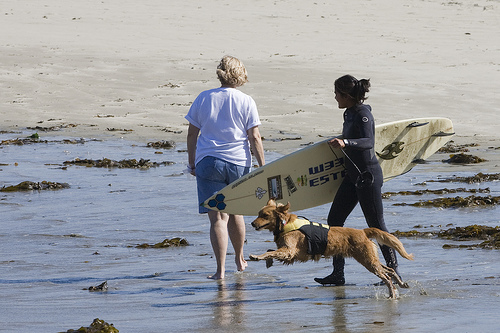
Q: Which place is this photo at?
A: It is at the beach.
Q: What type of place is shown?
A: It is a beach.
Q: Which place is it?
A: It is a beach.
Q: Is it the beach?
A: Yes, it is the beach.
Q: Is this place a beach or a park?
A: It is a beach.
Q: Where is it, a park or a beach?
A: It is a beach.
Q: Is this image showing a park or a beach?
A: It is showing a beach.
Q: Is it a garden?
A: No, it is a beach.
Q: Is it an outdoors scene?
A: Yes, it is outdoors.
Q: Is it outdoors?
A: Yes, it is outdoors.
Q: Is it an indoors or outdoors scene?
A: It is outdoors.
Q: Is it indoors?
A: No, it is outdoors.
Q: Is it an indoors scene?
A: No, it is outdoors.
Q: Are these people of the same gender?
A: Yes, all the people are female.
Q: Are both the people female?
A: Yes, all the people are female.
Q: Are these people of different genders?
A: No, all the people are female.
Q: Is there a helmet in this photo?
A: No, there are no helmets.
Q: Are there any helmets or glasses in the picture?
A: No, there are no helmets or glasses.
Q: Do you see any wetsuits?
A: Yes, there is a wetsuit.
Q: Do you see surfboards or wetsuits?
A: Yes, there is a wetsuit.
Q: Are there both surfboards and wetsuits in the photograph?
A: Yes, there are both a wetsuit and a surfboard.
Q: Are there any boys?
A: No, there are no boys.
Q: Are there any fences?
A: No, there are no fences.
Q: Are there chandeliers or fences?
A: No, there are no fences or chandeliers.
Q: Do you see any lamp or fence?
A: No, there are no fences or lamps.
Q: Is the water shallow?
A: Yes, the water is shallow.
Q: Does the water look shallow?
A: Yes, the water is shallow.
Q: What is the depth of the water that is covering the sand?
A: The water is shallow.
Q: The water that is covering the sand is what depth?
A: The water is shallow.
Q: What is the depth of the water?
A: The water is shallow.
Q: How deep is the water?
A: The water is shallow.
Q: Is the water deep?
A: No, the water is shallow.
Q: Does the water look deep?
A: No, the water is shallow.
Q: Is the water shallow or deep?
A: The water is shallow.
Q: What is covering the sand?
A: The water is covering the sand.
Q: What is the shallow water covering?
A: The water is covering the sand.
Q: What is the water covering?
A: The water is covering the sand.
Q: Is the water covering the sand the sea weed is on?
A: Yes, the water is covering the sand.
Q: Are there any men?
A: No, there are no men.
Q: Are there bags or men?
A: No, there are no men or bags.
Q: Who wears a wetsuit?
A: The lady wears a wetsuit.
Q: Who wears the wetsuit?
A: The lady wears a wetsuit.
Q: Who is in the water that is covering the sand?
A: The lady is in the water.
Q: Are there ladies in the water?
A: Yes, there is a lady in the water.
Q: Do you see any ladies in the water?
A: Yes, there is a lady in the water.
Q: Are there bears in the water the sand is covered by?
A: No, there is a lady in the water.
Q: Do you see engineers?
A: No, there are no engineers.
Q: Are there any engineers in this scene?
A: No, there are no engineers.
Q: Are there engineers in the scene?
A: No, there are no engineers.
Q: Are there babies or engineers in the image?
A: No, there are no engineers or babies.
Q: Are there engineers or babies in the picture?
A: No, there are no engineers or babies.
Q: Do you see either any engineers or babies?
A: No, there are no engineers or babies.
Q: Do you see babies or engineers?
A: No, there are no engineers or babies.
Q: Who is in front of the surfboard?
A: The lady is in front of the surfboard.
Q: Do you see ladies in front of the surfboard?
A: Yes, there is a lady in front of the surfboard.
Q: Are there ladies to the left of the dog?
A: Yes, there is a lady to the left of the dog.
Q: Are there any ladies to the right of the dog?
A: No, the lady is to the left of the dog.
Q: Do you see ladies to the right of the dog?
A: No, the lady is to the left of the dog.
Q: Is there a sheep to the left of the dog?
A: No, there is a lady to the left of the dog.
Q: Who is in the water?
A: The lady is in the water.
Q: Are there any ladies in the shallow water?
A: Yes, there is a lady in the water.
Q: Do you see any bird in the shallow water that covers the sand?
A: No, there is a lady in the water.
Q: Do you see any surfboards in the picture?
A: Yes, there is a surfboard.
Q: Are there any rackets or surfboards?
A: Yes, there is a surfboard.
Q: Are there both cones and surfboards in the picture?
A: No, there is a surfboard but no cones.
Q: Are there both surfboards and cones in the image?
A: No, there is a surfboard but no cones.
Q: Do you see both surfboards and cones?
A: No, there is a surfboard but no cones.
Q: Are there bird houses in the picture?
A: No, there are no bird houses.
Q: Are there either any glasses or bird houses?
A: No, there are no bird houses or glasses.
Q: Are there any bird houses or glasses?
A: No, there are no bird houses or glasses.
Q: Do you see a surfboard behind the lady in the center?
A: Yes, there is a surfboard behind the lady.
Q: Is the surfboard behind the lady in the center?
A: Yes, the surfboard is behind the lady.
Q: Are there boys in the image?
A: No, there are no boys.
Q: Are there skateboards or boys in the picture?
A: No, there are no boys or skateboards.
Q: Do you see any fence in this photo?
A: No, there are no fences.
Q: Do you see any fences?
A: No, there are no fences.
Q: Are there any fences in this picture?
A: No, there are no fences.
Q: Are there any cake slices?
A: No, there are no cake slices.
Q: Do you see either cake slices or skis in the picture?
A: No, there are no cake slices or skis.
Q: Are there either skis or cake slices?
A: No, there are no cake slices or skis.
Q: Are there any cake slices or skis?
A: No, there are no cake slices or skis.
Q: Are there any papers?
A: No, there are no papers.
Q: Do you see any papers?
A: No, there are no papers.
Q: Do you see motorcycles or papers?
A: No, there are no papers or motorcycles.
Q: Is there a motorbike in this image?
A: No, there are no motorcycles.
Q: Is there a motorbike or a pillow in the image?
A: No, there are no motorcycles or pillows.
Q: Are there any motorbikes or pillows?
A: No, there are no motorbikes or pillows.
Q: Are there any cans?
A: No, there are no cans.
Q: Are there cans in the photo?
A: No, there are no cans.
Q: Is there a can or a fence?
A: No, there are no cans or fences.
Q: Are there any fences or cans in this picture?
A: No, there are no cans or fences.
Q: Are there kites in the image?
A: No, there are no kites.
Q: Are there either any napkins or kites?
A: No, there are no kites or napkins.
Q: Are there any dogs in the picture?
A: Yes, there is a dog.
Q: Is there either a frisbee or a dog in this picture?
A: Yes, there is a dog.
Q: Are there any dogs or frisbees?
A: Yes, there is a dog.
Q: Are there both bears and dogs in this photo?
A: No, there is a dog but no bears.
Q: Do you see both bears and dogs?
A: No, there is a dog but no bears.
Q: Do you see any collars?
A: No, there are no collars.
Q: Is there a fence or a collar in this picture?
A: No, there are no collars or fences.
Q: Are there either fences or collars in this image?
A: No, there are no collars or fences.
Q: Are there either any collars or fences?
A: No, there are no collars or fences.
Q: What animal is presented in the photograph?
A: The animal is a dog.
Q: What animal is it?
A: The animal is a dog.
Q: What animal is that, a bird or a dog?
A: This is a dog.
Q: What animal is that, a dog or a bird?
A: This is a dog.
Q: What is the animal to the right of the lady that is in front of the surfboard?
A: The animal is a dog.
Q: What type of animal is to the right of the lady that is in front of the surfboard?
A: The animal is a dog.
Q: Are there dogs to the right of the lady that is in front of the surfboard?
A: Yes, there is a dog to the right of the lady.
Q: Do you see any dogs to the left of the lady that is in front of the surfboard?
A: No, the dog is to the right of the lady.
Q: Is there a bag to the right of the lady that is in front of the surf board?
A: No, there is a dog to the right of the lady.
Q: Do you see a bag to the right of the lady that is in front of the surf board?
A: No, there is a dog to the right of the lady.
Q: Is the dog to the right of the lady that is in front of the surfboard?
A: Yes, the dog is to the right of the lady.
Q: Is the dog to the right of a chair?
A: No, the dog is to the right of the lady.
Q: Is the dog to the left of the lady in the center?
A: No, the dog is to the right of the lady.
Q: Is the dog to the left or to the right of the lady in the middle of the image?
A: The dog is to the right of the lady.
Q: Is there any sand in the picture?
A: Yes, there is sand.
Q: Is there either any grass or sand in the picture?
A: Yes, there is sand.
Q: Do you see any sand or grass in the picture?
A: Yes, there is sand.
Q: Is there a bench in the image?
A: No, there are no benches.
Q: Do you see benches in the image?
A: No, there are no benches.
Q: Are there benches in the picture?
A: No, there are no benches.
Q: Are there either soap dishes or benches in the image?
A: No, there are no benches or soap dishes.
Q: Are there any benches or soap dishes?
A: No, there are no benches or soap dishes.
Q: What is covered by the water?
A: The sand is covered by the water.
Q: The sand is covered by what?
A: The sand is covered by the water.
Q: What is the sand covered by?
A: The sand is covered by the water.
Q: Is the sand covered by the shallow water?
A: Yes, the sand is covered by the water.